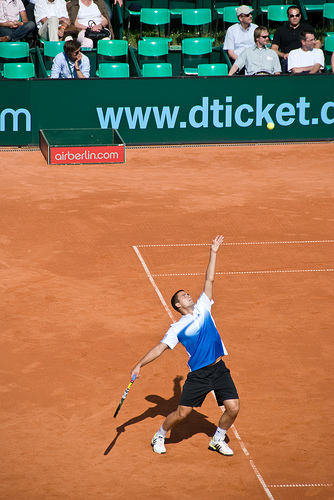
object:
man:
[113, 235, 245, 458]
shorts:
[179, 357, 239, 410]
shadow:
[97, 375, 225, 446]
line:
[130, 244, 180, 326]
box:
[40, 128, 127, 163]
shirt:
[163, 293, 231, 374]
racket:
[112, 371, 140, 419]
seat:
[141, 58, 177, 77]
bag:
[88, 19, 111, 39]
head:
[169, 286, 196, 313]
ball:
[265, 117, 276, 132]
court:
[2, 145, 331, 496]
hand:
[208, 232, 228, 253]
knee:
[222, 394, 247, 424]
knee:
[174, 404, 193, 425]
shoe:
[148, 423, 171, 455]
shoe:
[203, 433, 235, 454]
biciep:
[163, 329, 178, 347]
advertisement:
[2, 78, 334, 150]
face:
[181, 289, 197, 305]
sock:
[157, 425, 169, 437]